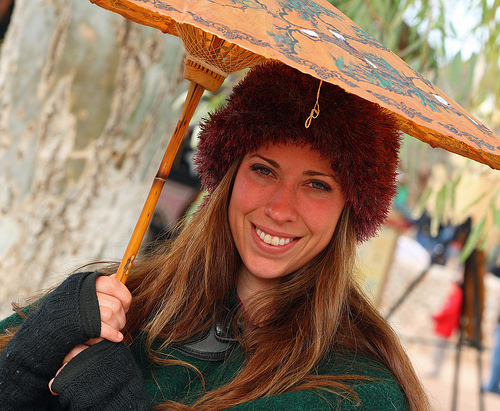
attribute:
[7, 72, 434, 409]
lady — smiling, long, looking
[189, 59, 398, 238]
hat — red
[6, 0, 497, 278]
umbrella — orange, decorated, wood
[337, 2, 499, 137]
leaves — green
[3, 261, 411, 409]
coat — green, long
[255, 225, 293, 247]
teeth — white